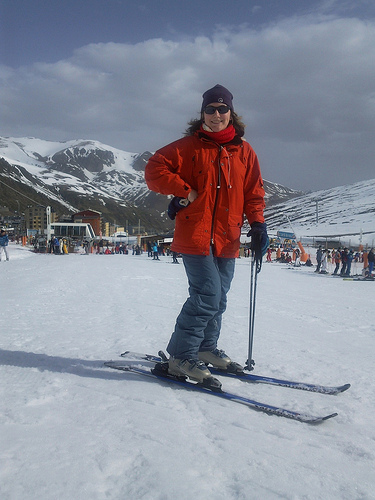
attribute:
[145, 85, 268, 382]
woman — smiling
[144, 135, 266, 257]
jacket — red, orange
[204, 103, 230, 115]
sunglasses — black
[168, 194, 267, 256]
gloves — black, blue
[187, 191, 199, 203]
hand — bare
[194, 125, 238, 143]
scarf — red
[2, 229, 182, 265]
people — walking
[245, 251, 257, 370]
poles — black, metal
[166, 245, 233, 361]
pants — gray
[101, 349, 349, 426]
skis — blue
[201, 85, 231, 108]
hat — blue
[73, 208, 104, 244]
building — brown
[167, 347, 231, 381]
boots — gray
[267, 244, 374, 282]
group — skiing